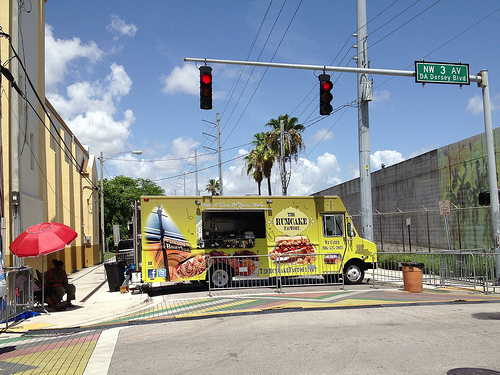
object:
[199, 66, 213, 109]
signal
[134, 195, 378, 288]
truck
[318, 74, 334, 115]
signal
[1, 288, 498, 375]
road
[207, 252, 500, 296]
guardrail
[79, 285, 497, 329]
crosswalk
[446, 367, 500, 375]
manhole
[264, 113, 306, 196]
tree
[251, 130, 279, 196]
tree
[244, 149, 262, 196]
tree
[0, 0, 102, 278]
building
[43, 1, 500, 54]
sky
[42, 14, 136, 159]
clouds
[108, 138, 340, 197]
clouds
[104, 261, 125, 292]
can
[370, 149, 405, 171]
clouds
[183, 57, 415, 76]
pole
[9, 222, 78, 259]
umbrella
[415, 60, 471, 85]
sign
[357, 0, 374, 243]
pole